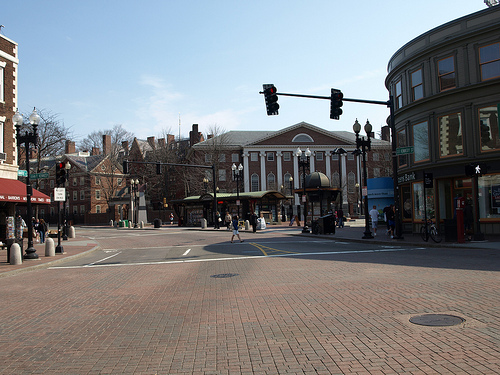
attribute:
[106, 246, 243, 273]
lines — white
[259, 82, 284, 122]
light — red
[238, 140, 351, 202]
columns — white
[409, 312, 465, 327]
cover — black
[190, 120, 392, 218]
building — large, brown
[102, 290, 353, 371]
bricks — red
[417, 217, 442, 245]
bike — parked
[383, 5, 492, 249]
building — curved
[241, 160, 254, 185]
column — white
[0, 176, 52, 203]
awning — red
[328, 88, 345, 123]
light — black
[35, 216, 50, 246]
person — walking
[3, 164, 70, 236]
awning — red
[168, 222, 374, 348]
street — brick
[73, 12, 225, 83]
sky — blue, clear